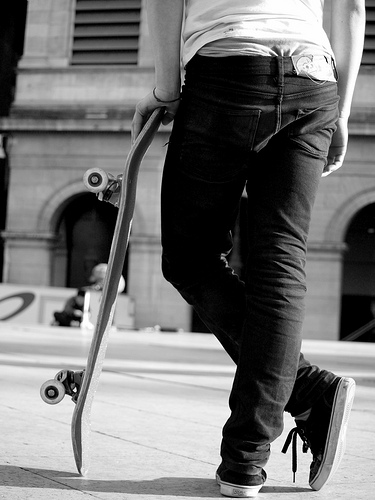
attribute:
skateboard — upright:
[38, 105, 170, 475]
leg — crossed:
[159, 101, 350, 487]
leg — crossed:
[213, 141, 322, 496]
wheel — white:
[85, 165, 110, 200]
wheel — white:
[41, 376, 67, 407]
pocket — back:
[179, 94, 270, 184]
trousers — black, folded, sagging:
[156, 52, 342, 473]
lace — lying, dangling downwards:
[286, 427, 304, 485]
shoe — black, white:
[295, 374, 352, 492]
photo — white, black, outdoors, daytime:
[9, 1, 374, 499]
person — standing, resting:
[122, 0, 371, 498]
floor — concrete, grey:
[6, 345, 374, 499]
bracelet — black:
[149, 89, 183, 107]